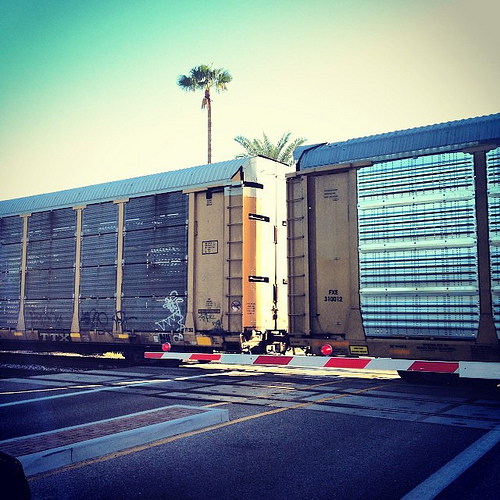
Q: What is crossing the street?
A: Train.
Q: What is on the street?
A: Crossing bar.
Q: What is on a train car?
A: Metal.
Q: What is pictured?
A: Two train cars.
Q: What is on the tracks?
A: A train.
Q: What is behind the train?
A: A palm tree.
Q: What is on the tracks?
A: A train.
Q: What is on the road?
A: A median.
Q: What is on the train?
A: Steel shutters.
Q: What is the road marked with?
A: White and yellow color.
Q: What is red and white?
A: Caution guard.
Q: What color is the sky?
A: Blue.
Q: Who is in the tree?
A: No one.